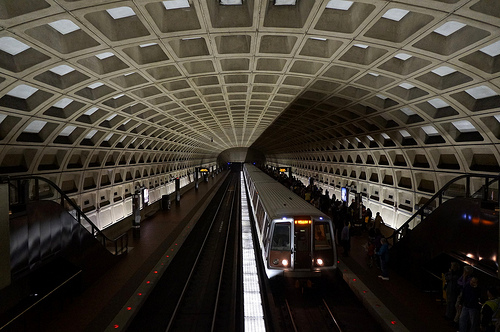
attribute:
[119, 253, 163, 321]
lights — red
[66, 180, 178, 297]
dock — edge, subway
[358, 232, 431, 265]
shirt — blue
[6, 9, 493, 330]
subway tunnel — busy, underground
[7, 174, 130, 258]
stairs — pictured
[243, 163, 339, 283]
train — tr`ack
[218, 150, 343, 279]
train — escalator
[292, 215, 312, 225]
sign — lit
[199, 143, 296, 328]
divider — concrete, lighted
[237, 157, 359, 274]
train — tracks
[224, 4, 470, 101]
cieling — white, glass, concrete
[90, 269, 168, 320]
reflectors — red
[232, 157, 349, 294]
train — subway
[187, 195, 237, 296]
tracks — empty, set, train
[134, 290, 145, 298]
red light — small, warning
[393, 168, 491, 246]
stairs — pictured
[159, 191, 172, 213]
trash receptacle — pictured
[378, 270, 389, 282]
shoes — white